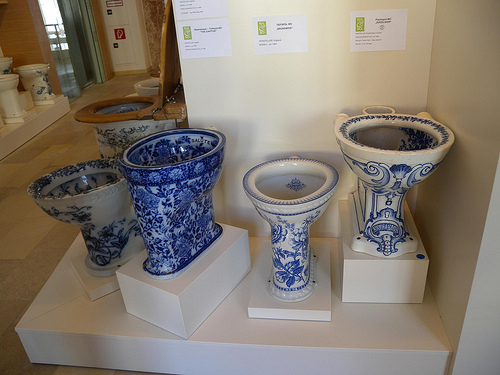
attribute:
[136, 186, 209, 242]
flowers — white, blue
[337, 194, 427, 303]
pedastal — white, bases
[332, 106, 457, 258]
bowls — toilet 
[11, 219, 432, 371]
platform — large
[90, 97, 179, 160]
toilet bowl — blue, white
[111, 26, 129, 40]
sign — red, white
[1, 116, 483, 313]
toilet bowls — toilet , without lids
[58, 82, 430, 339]
toilets — display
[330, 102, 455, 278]
vase — behind 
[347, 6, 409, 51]
paper — white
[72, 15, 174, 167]
toilet seat — wooden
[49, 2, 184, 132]
toilet seat — open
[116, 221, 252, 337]
stand — white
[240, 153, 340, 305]
toilet — designed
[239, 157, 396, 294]
toilet — white 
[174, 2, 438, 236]
wall — cream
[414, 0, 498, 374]
wall — cream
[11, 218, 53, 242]
tiles — beige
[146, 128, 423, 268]
vases — white, blue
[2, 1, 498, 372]
store — fancy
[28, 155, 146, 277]
toilet bowl — blue, white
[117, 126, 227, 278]
toilet bowl — blue, white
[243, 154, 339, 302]
toilet bowl — blue, white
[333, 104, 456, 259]
toilet bowl — white, blue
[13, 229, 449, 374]
platform — white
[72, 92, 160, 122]
seat — wood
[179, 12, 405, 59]
descriptions — vase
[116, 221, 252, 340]
box — rectangular 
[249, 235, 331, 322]
box — rectangular 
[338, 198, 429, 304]
box — rectangular 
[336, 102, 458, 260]
toilets — blue , white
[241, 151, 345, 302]
toilets — white, blue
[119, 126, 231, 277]
toilets — white, blue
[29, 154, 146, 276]
toilets — white, blue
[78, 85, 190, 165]
toilets — white, blue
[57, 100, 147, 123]
seat — large, wood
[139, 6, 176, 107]
cover — wood, large